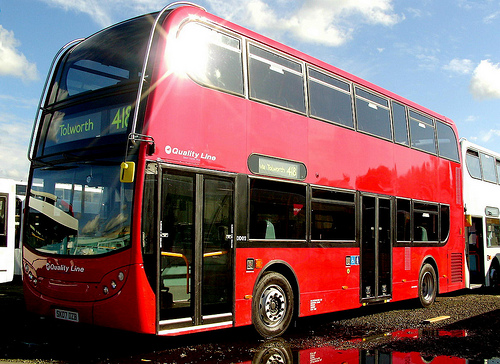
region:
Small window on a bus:
[33, 32, 171, 96]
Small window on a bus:
[170, 9, 245, 107]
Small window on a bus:
[242, 28, 309, 124]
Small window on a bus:
[304, 59, 356, 143]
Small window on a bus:
[350, 76, 400, 146]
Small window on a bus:
[385, 95, 410, 146]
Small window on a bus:
[404, 101, 436, 152]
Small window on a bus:
[436, 111, 467, 172]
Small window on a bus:
[396, 193, 411, 249]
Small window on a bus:
[238, 163, 315, 273]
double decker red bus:
[21, 4, 469, 334]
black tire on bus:
[256, 268, 294, 334]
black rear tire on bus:
[420, 264, 445, 307]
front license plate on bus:
[49, 305, 83, 320]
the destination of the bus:
[49, 107, 140, 142]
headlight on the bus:
[113, 270, 126, 279]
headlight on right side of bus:
[17, 259, 33, 274]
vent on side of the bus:
[447, 247, 468, 283]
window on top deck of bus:
[247, 38, 305, 110]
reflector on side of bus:
[253, 257, 262, 271]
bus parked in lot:
[18, 3, 480, 334]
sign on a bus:
[41, 111, 151, 141]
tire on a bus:
[246, 267, 317, 337]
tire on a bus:
[413, 252, 448, 302]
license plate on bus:
[40, 290, 98, 330]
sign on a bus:
[231, 150, 313, 190]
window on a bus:
[28, 171, 118, 256]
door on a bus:
[161, 158, 231, 333]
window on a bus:
[247, 175, 307, 246]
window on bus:
[351, 79, 399, 149]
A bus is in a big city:
[16, 5, 494, 361]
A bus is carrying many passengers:
[25, 5, 480, 360]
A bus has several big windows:
[37, 20, 445, 360]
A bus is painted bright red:
[16, 12, 461, 357]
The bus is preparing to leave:
[25, 2, 451, 354]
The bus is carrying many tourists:
[16, 10, 451, 348]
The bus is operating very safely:
[22, 12, 450, 357]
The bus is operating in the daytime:
[5, 5, 455, 360]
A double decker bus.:
[7, 4, 467, 339]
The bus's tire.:
[250, 273, 295, 340]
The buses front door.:
[160, 166, 240, 332]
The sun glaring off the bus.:
[171, 27, 212, 87]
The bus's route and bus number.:
[43, 108, 133, 137]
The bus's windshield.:
[23, 162, 128, 265]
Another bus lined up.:
[460, 133, 496, 296]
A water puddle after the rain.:
[248, 337, 479, 358]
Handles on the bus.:
[26, 35, 56, 165]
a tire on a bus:
[245, 266, 300, 340]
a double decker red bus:
[7, 5, 473, 331]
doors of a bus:
[147, 158, 242, 335]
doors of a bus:
[350, 184, 400, 309]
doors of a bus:
[147, 153, 248, 336]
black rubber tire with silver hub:
[246, 266, 300, 340]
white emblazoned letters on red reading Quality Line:
[41, 259, 84, 276]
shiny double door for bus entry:
[155, 159, 234, 326]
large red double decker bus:
[18, 5, 469, 336]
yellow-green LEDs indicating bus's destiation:
[40, 109, 135, 137]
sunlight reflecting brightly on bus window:
[168, 12, 248, 90]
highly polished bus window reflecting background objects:
[28, 172, 129, 251]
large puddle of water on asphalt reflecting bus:
[228, 326, 497, 361]